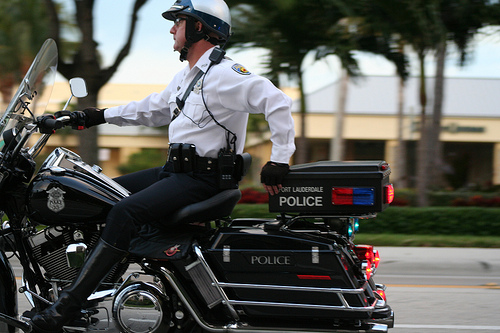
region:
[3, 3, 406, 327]
a policeman on a motorcycle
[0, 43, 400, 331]
a black police motorcycle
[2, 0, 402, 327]
a Fort Lauderdale police office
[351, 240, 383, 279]
the taillight of a motorcyle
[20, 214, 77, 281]
the engine of a motorcycle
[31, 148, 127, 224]
the gas-tank of a motorcycle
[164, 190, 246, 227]
the seat of a motorcycle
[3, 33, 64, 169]
the windshield of a motorcycle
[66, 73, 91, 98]
the mirror of a motorcycle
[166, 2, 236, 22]
a white and black helmet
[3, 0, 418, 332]
a police in a motorcycle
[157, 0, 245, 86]
gray helmet on head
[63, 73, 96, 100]
a mirror on right side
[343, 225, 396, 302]
red lights on back of motorcycle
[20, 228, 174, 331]
the engine of motorcycle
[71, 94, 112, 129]
hand on handle of motorcycle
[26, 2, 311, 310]
policeman wears white shirt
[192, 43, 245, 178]
the walky talky of policeman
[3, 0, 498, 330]
trees behind the motorcycle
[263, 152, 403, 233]
a box behind the motorcycle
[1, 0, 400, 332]
Policeman riding a motorcycle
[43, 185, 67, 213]
Police shield logo in white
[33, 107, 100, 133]
Motorcycle handlebars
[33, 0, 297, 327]
Policeman in a white shirt and black pants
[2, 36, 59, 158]
Clear motorcycle windshield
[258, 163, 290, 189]
Black gloves without fingertips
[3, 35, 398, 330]
Black motorcyle with police written on the side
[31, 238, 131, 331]
Shiny black boot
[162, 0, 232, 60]
White and dark blue helmet with black chin strap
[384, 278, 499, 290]
Yellow line painted on the street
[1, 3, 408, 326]
a police officer on a motor cycle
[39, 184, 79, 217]
a shield that says police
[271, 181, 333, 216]
white letters that say Fort Lauderdale Police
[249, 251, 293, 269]
white letters that say police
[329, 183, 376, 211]
a red and blue light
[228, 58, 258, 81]
an agency patch on the police uniform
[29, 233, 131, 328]
black dress boots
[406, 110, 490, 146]
a sign with green letters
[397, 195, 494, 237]
a row of green bushes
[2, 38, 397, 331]
a black motorcycle on street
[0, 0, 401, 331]
a police officer on motorcycle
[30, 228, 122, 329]
a black leather boot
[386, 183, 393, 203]
a red tail light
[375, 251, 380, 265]
a red tail light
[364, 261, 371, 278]
a red tail light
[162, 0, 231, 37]
a silver protective helmet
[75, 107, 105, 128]
a black motorcycle glove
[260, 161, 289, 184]
a black motorcycle glove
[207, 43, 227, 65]
a two way radio